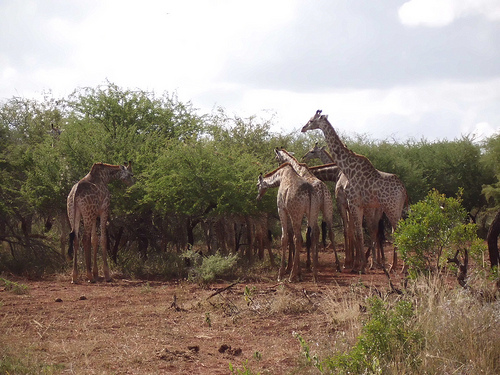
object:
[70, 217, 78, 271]
legs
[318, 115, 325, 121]
giraffe ears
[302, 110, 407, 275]
giraffes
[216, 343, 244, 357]
stone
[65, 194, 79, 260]
tail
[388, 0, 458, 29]
clouds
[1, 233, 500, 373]
ground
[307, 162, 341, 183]
giraffe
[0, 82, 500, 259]
trees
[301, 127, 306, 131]
nose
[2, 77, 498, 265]
row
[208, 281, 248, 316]
branches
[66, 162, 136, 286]
giraffe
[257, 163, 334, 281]
giraffe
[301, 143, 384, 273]
giraffe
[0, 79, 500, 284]
leaves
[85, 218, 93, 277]
leg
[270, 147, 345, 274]
giraffe